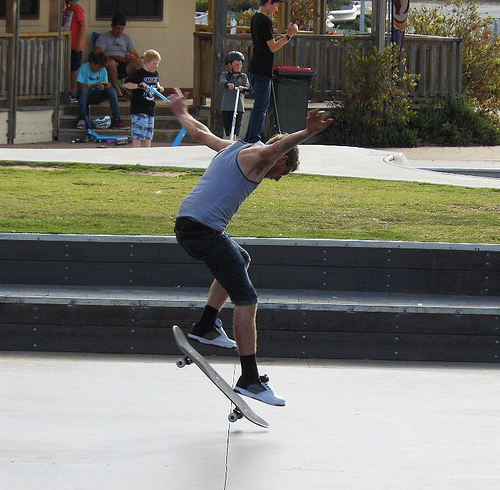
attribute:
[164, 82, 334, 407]
person — skateboarding, young, jumping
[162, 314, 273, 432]
skateboard — black, wood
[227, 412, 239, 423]
wheel — round, white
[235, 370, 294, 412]
shoe — black, white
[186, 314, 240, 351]
shoe — black, white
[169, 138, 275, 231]
tank top — light blue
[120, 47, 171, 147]
child — sitting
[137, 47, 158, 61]
hair — brown, blonde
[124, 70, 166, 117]
shirt — black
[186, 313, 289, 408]
shoes — black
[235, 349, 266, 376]
socks — black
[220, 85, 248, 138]
scooter — blue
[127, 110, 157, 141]
shorts — blue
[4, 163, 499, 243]
area — grassy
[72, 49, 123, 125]
boy — sitting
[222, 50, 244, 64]
helmet — black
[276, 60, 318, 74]
lid — red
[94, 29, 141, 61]
shirt — black, gray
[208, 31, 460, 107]
rail — wood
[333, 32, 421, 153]
shrub — green